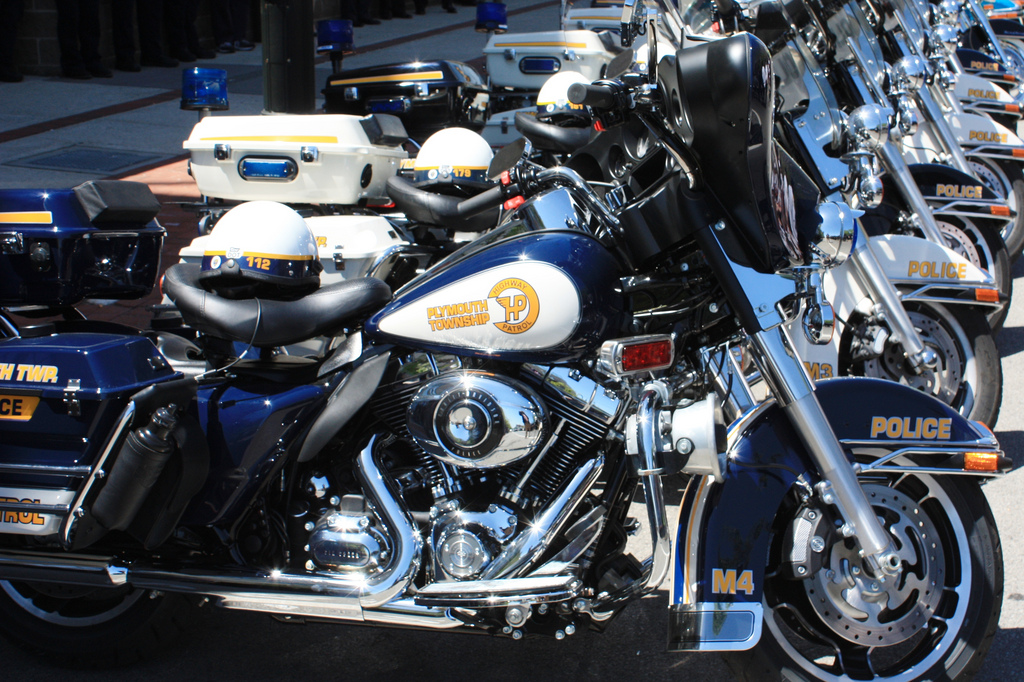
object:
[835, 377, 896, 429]
ground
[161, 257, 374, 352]
seat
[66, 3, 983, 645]
outdoors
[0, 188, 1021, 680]
motorcycle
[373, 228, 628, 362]
gas tank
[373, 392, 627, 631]
motor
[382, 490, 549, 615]
chrome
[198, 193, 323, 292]
helmet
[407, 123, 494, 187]
helmet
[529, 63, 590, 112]
helmet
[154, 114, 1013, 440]
motorcycle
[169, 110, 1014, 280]
motorcycle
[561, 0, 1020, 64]
motorcycle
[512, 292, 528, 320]
letter